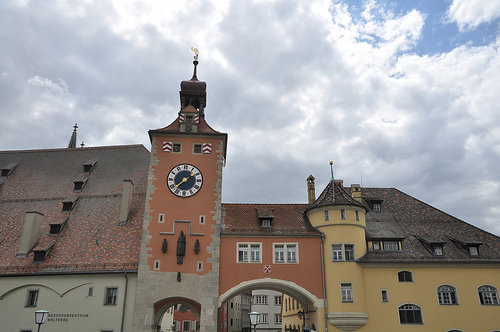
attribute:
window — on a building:
[284, 241, 297, 261]